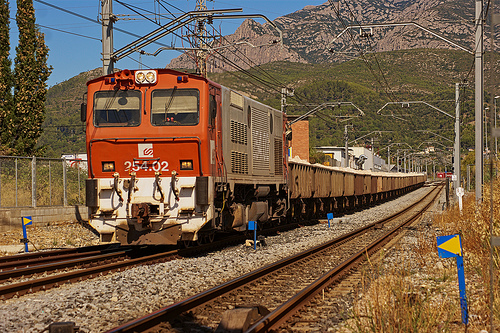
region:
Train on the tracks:
[82, 69, 427, 245]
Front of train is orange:
[85, 69, 220, 175]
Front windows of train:
[92, 90, 197, 125]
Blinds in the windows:
[95, 93, 197, 111]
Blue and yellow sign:
[22, 216, 32, 250]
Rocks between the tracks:
[5, 293, 149, 328]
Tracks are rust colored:
[112, 247, 313, 331]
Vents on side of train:
[232, 103, 273, 177]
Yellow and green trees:
[1, 1, 50, 153]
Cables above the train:
[1, 1, 427, 168]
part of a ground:
[193, 255, 210, 273]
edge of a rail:
[308, 273, 361, 327]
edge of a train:
[190, 142, 225, 204]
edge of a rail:
[328, 279, 341, 292]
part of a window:
[162, 98, 192, 138]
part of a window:
[226, 207, 241, 234]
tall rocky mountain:
[161, 0, 498, 74]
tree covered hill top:
[34, 46, 499, 187]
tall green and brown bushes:
[0, 0, 56, 174]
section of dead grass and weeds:
[328, 176, 499, 331]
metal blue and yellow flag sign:
[432, 230, 467, 322]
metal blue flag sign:
[245, 217, 257, 248]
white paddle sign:
[454, 185, 466, 215]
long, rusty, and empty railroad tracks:
[103, 176, 450, 331]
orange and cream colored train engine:
[73, 67, 290, 249]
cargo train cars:
[284, 153, 429, 226]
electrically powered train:
[76, 67, 431, 260]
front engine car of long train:
[80, 63, 293, 257]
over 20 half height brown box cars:
[285, 154, 432, 225]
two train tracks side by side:
[2, 243, 180, 298]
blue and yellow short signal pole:
[434, 231, 475, 332]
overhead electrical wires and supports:
[5, 1, 493, 218]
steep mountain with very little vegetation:
[158, 0, 497, 74]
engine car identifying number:
[120, 156, 175, 177]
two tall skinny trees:
[2, 27, 52, 154]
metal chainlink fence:
[0, 152, 89, 210]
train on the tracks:
[73, 71, 440, 253]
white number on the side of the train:
[119, 151, 173, 178]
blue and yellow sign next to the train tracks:
[426, 223, 475, 323]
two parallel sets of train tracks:
[3, 171, 454, 332]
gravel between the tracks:
[19, 238, 275, 331]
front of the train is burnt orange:
[87, 80, 217, 173]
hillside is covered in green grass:
[257, 59, 490, 150]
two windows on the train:
[97, 88, 201, 129]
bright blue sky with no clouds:
[2, 1, 322, 83]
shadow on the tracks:
[161, 305, 226, 332]